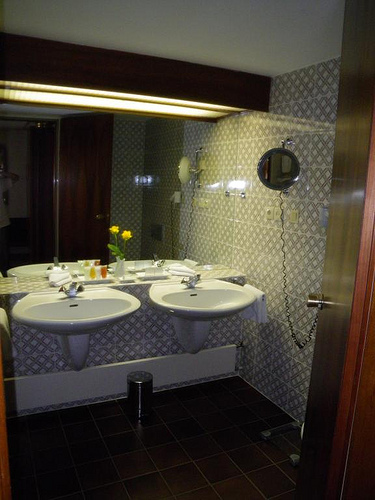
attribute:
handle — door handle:
[301, 288, 327, 310]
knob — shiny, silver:
[305, 294, 319, 308]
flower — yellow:
[104, 220, 131, 259]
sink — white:
[9, 284, 140, 367]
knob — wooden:
[301, 285, 327, 321]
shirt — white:
[0, 178, 14, 228]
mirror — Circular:
[256, 146, 300, 191]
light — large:
[2, 80, 253, 123]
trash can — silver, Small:
[127, 370, 153, 417]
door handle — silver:
[305, 294, 336, 309]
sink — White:
[144, 280, 258, 353]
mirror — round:
[256, 148, 304, 193]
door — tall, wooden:
[298, 5, 374, 495]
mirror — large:
[1, 94, 240, 289]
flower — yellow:
[120, 230, 132, 241]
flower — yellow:
[107, 225, 118, 233]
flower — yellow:
[118, 228, 137, 258]